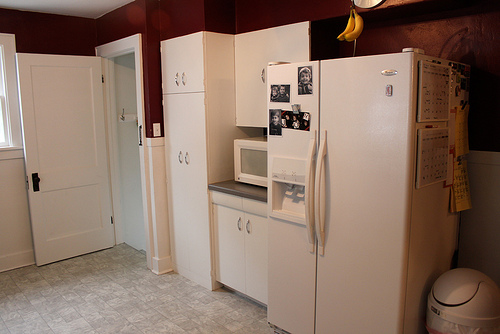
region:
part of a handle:
[282, 142, 339, 222]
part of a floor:
[133, 266, 163, 294]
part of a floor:
[119, 298, 136, 316]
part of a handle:
[314, 210, 331, 256]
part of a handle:
[305, 188, 332, 279]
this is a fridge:
[268, 55, 415, 324]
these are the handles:
[298, 149, 333, 241]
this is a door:
[21, 57, 104, 256]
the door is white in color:
[32, 100, 101, 171]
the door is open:
[94, 40, 147, 249]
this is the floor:
[70, 263, 146, 328]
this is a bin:
[431, 270, 492, 330]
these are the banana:
[334, 12, 366, 44]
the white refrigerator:
[266, 47, 460, 332]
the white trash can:
[423, 266, 499, 332]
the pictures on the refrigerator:
[268, 67, 313, 137]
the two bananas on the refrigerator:
[336, 4, 363, 41]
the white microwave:
[233, 137, 267, 187]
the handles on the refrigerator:
[303, 129, 328, 254]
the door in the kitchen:
[15, 49, 115, 266]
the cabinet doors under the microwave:
[213, 202, 268, 307]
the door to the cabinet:
[232, 28, 266, 129]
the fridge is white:
[267, 49, 460, 332]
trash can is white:
[427, 269, 499, 332]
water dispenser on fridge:
[271, 179, 306, 217]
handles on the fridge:
[305, 130, 328, 252]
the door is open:
[16, 50, 118, 265]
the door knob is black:
[32, 170, 39, 191]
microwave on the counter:
[233, 136, 268, 187]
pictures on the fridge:
[266, 65, 312, 135]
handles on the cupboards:
[236, 217, 250, 232]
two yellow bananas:
[337, 8, 359, 40]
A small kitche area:
[18, 24, 479, 325]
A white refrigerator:
[265, 41, 416, 316]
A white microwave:
[226, 129, 263, 188]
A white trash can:
[423, 262, 498, 330]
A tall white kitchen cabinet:
[160, 32, 221, 299]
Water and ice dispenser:
[271, 173, 309, 223]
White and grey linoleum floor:
[51, 272, 166, 332]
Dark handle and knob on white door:
[24, 162, 49, 197]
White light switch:
[148, 122, 165, 135]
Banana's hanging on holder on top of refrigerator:
[331, 8, 374, 42]